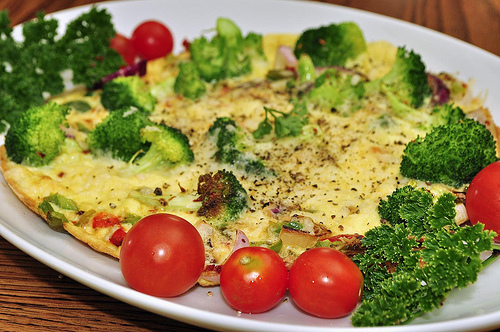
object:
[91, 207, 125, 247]
chunk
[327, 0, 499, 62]
corner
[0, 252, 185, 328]
table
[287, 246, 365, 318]
tomato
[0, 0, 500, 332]
plate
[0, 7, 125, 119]
parsley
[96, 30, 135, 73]
tomato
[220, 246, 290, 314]
tomato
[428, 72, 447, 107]
ham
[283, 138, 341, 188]
seasoning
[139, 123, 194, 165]
broccoli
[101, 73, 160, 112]
broccoli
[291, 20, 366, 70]
broccoli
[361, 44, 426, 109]
broccoli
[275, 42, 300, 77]
onions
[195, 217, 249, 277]
onions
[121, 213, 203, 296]
cherry tomato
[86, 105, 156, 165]
broccoli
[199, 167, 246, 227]
broccoli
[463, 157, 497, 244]
tomato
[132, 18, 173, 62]
tomato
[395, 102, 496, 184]
broccoli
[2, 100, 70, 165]
broccoli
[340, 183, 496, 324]
broccoli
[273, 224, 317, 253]
onion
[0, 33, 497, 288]
egg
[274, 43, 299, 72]
ham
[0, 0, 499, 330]
cafe.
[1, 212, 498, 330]
foreground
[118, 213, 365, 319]
row